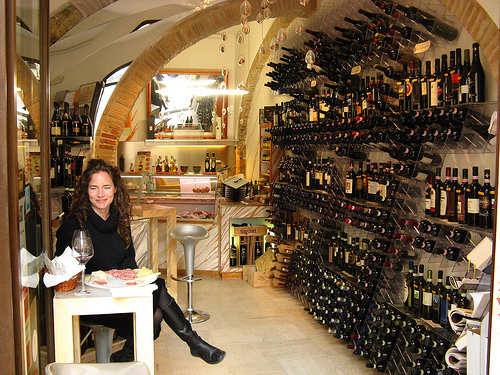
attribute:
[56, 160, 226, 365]
woman — sitting, smiling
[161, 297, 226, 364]
boot — black, calf-length, knee-high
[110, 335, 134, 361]
boot — black, knee-high, calf-length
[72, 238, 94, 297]
wine glass — empty, present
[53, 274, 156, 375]
table — white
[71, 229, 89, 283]
wine glass — empty, present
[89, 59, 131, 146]
window — present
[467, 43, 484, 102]
wine bottle — glass, present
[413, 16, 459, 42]
wine bottle — glass, present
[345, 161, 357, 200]
wine bottle — glass, present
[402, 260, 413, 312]
wine bottle — glass, present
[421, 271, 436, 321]
wine bottle — glass, present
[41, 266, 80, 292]
basket — brown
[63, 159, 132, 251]
hair — curly, dark, brown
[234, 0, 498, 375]
wall — full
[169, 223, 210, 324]
stool — silver, designer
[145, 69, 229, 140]
mirror — present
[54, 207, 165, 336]
dress — black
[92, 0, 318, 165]
archway — brick, present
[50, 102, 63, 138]
wine — present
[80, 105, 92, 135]
wine — present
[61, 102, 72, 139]
wine — present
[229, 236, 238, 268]
wine — present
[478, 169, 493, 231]
wine — present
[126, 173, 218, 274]
deli counter — present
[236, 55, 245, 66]
drop — glass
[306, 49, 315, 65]
drop — glass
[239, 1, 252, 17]
drop — glass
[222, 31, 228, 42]
drop — glass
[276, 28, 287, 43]
drop — glass